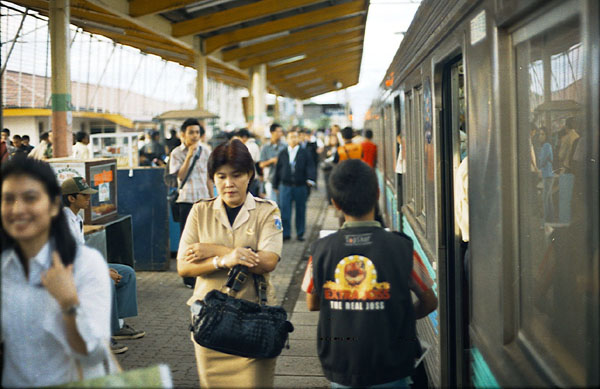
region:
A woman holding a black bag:
[150, 107, 305, 379]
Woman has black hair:
[169, 106, 301, 232]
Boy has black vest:
[293, 143, 418, 387]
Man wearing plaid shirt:
[151, 86, 239, 252]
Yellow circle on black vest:
[299, 205, 457, 349]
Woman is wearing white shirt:
[4, 164, 144, 379]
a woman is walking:
[1, 155, 170, 387]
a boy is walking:
[299, 156, 440, 387]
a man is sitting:
[60, 177, 146, 357]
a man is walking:
[170, 117, 213, 286]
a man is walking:
[270, 132, 314, 243]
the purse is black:
[188, 264, 294, 360]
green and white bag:
[49, 363, 169, 387]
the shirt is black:
[310, 228, 415, 387]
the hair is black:
[328, 156, 378, 217]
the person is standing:
[332, 176, 422, 383]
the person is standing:
[205, 141, 277, 382]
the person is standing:
[0, 168, 90, 383]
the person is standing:
[162, 106, 225, 243]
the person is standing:
[259, 127, 286, 205]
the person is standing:
[286, 124, 307, 234]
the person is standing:
[336, 125, 356, 167]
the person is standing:
[354, 122, 377, 172]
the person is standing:
[141, 122, 170, 158]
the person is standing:
[318, 120, 341, 154]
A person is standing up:
[304, 148, 438, 382]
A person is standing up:
[177, 147, 285, 387]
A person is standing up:
[165, 120, 211, 285]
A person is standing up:
[280, 125, 318, 232]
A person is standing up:
[264, 115, 294, 187]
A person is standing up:
[340, 127, 355, 162]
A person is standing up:
[352, 124, 375, 169]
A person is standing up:
[315, 129, 345, 201]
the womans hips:
[178, 271, 296, 350]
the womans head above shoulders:
[204, 134, 263, 206]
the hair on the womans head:
[198, 133, 259, 181]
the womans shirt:
[177, 193, 294, 295]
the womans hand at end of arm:
[218, 245, 264, 276]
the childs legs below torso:
[319, 378, 407, 387]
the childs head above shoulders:
[319, 153, 392, 225]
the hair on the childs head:
[330, 157, 378, 211]